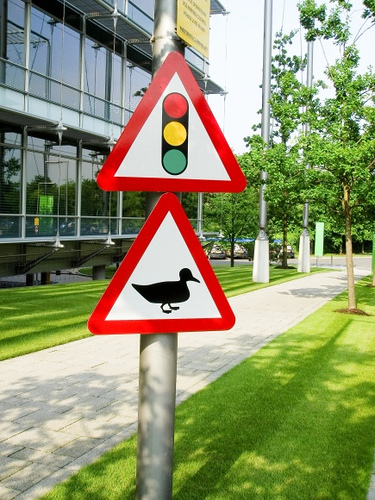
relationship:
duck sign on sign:
[83, 192, 238, 335] [75, 190, 247, 366]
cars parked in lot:
[201, 232, 297, 261] [197, 215, 370, 265]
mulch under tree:
[333, 305, 369, 316] [271, 45, 374, 309]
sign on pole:
[88, 191, 234, 332] [128, 2, 191, 498]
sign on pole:
[178, 4, 216, 66] [128, 335, 182, 495]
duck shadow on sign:
[128, 264, 201, 309] [90, 190, 243, 344]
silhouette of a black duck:
[131, 267, 201, 313] [130, 268, 200, 313]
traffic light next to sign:
[141, 77, 203, 200] [96, 45, 254, 195]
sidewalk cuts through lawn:
[3, 265, 369, 496] [2, 263, 374, 498]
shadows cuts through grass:
[10, 292, 373, 497] [87, 296, 361, 492]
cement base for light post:
[251, 238, 270, 284] [256, 1, 273, 240]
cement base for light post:
[296, 235, 311, 274] [301, 0, 316, 235]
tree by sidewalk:
[242, 110, 360, 229] [254, 286, 348, 394]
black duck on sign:
[132, 266, 200, 312] [82, 193, 240, 340]